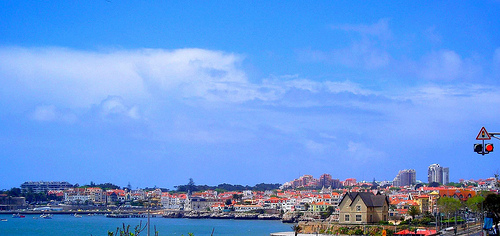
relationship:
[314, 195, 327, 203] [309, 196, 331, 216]
roof on building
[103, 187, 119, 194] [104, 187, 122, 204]
roof on building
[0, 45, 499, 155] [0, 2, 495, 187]
clouds in sky